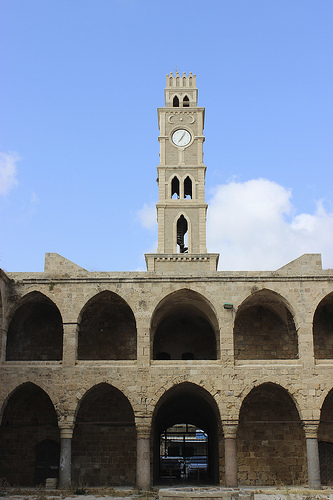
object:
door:
[40, 436, 61, 488]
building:
[143, 67, 219, 273]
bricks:
[236, 309, 298, 358]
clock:
[172, 129, 191, 146]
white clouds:
[214, 181, 292, 251]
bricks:
[222, 290, 237, 300]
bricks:
[136, 271, 151, 365]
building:
[0, 73, 333, 500]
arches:
[171, 175, 193, 199]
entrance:
[151, 382, 223, 487]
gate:
[159, 423, 208, 483]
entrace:
[236, 382, 309, 486]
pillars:
[57, 427, 320, 484]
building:
[0, 253, 332, 498]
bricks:
[0, 69, 332, 497]